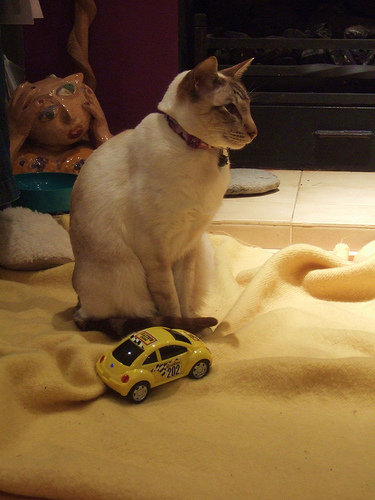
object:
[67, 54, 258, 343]
cat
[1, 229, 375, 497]
blanket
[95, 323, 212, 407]
beetle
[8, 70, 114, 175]
statue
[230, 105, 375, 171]
drawer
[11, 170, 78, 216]
bowl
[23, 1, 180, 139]
wall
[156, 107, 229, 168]
collar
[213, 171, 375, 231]
floor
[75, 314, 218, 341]
tail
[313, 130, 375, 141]
handle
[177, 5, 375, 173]
structure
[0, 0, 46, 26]
paper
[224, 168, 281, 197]
stone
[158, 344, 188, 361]
window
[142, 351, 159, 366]
window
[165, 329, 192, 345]
window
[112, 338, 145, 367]
window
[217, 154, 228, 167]
pendant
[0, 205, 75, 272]
pillow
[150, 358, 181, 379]
graphic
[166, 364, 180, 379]
numbering